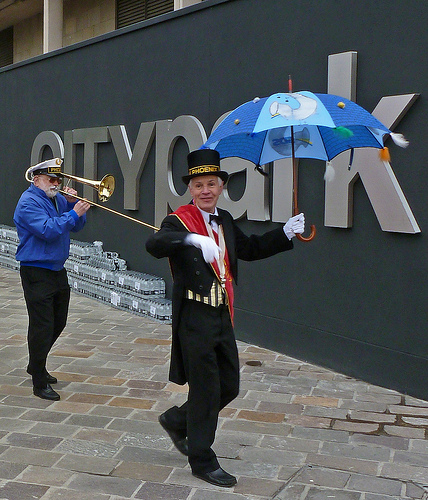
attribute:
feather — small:
[377, 145, 392, 162]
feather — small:
[387, 131, 410, 147]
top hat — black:
[179, 149, 230, 188]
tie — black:
[205, 206, 240, 232]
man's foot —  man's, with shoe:
[14, 368, 88, 409]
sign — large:
[1, 4, 422, 404]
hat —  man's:
[173, 143, 236, 180]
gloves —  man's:
[177, 205, 299, 267]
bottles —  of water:
[76, 252, 171, 337]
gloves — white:
[184, 234, 223, 263]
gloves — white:
[282, 212, 313, 235]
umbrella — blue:
[214, 82, 387, 242]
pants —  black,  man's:
[165, 301, 240, 473]